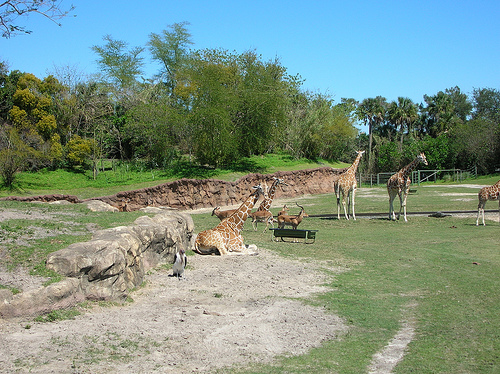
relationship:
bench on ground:
[272, 222, 320, 248] [176, 177, 500, 372]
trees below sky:
[7, 30, 494, 171] [4, 3, 497, 103]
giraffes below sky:
[197, 149, 499, 256] [4, 3, 497, 103]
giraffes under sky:
[197, 149, 499, 256] [4, 3, 497, 103]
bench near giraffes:
[272, 222, 320, 248] [197, 149, 499, 256]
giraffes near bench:
[197, 149, 499, 256] [272, 222, 320, 248]